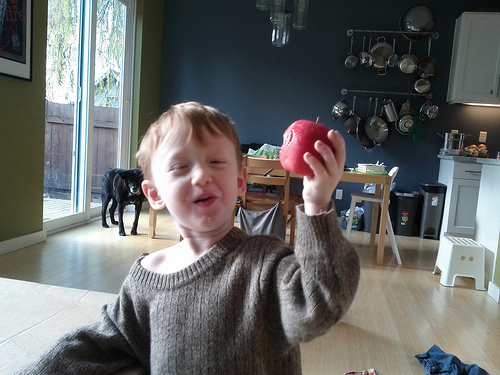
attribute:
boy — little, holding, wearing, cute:
[116, 115, 350, 365]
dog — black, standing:
[83, 151, 148, 216]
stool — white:
[403, 220, 499, 286]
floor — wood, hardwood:
[368, 259, 459, 340]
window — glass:
[57, 33, 115, 171]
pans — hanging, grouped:
[319, 38, 445, 154]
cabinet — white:
[433, 164, 485, 217]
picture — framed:
[5, 28, 43, 97]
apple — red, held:
[284, 108, 336, 188]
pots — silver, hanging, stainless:
[340, 51, 405, 83]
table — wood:
[359, 151, 415, 226]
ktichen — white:
[386, 40, 497, 224]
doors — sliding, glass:
[47, 18, 92, 215]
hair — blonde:
[138, 109, 224, 160]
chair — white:
[362, 185, 419, 258]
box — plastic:
[382, 202, 422, 229]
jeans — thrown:
[403, 324, 451, 374]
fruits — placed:
[246, 145, 280, 173]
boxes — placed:
[384, 161, 447, 245]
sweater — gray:
[127, 221, 412, 348]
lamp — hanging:
[253, 10, 316, 52]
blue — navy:
[190, 26, 295, 139]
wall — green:
[5, 102, 57, 212]